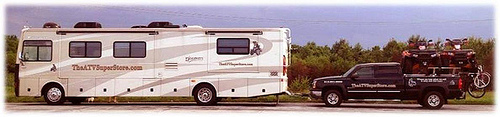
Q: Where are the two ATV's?
A: On the back of the pick up truck.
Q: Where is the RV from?
A: The ATV super store.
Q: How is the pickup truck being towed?
A: Via connection with the RV.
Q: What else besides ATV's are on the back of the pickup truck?
A: 2 bicycles.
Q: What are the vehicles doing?
A: An RV Towing a truck.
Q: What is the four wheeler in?
A: The trunk of the truck.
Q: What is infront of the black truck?
A: An RV.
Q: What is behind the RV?
A: A black truck.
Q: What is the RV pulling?
A: A black truck.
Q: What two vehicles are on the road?
A: An RV, and a Truck.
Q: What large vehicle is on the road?
A: An RV.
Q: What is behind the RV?
A: A truck.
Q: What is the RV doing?
A: Towing a truck.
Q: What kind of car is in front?
A: Camper.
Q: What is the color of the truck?
A: Black.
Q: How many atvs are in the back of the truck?
A: 2.